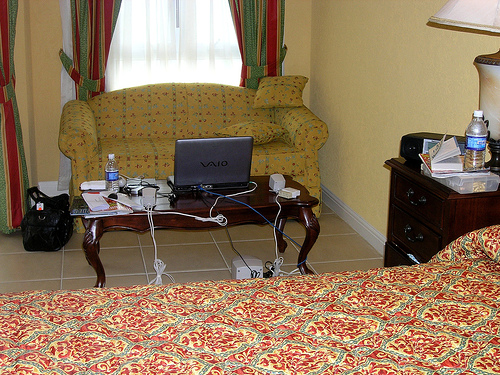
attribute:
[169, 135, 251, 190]
laptop — grey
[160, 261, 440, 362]
bed spread — red, yellow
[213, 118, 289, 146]
pillow — matching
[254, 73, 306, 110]
pillow — matching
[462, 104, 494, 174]
bottle — plastic, water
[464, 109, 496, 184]
bottle — plastic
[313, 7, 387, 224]
wall — yellow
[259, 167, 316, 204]
speaker — grey, plastic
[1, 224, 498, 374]
spread — print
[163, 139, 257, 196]
laptop — open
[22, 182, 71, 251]
black bag — leather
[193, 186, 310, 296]
cord — blue, electrical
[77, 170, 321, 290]
coffee table — brown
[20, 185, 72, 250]
bag — black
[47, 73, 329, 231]
couch — yellow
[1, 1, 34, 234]
curtain — green, red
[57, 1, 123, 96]
curtain — green, red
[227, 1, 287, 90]
curtain — green, red